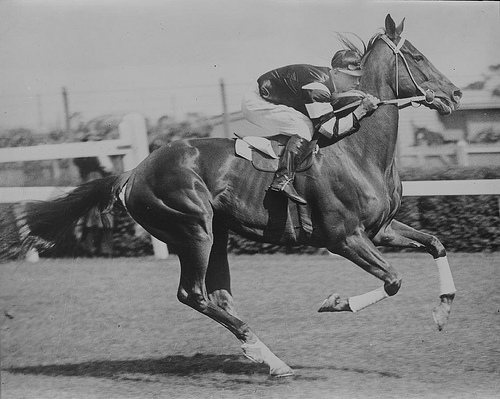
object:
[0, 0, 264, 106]
clouds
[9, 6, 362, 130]
sky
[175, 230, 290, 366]
legs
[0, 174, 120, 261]
hair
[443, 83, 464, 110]
snout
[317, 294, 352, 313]
hoof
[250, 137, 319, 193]
cage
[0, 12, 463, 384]
horse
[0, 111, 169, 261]
fence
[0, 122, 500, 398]
enclosure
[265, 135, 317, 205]
boot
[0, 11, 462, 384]
jockey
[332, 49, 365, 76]
cap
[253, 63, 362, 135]
shirt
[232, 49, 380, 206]
man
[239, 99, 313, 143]
pants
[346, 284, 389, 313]
ankles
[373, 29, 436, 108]
bridle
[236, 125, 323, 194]
saddle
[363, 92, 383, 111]
hand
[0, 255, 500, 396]
track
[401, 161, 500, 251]
shrubs